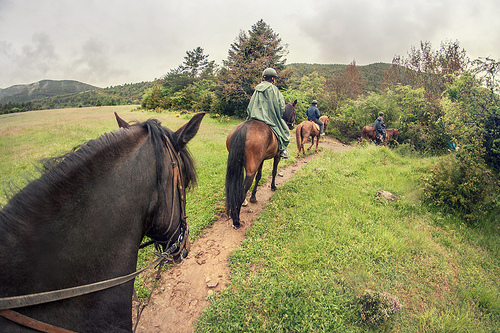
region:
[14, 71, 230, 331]
this is a horse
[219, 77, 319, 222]
this a brown horse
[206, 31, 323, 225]
person riding a horse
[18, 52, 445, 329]
group of people riding horses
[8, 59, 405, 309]
horses walking on a trail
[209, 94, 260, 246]
black tail on horse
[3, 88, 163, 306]
black mane on horse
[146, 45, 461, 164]
green brush next to trail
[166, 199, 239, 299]
horse foot prints on trail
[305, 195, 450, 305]
A patch of green and brown grass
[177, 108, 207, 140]
A horse's ear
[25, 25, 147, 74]
Cloud cover in the sky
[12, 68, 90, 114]
Mountains in the distance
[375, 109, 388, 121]
The person is wearing a helmet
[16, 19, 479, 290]
this is a nature setting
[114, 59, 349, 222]
these are horse riders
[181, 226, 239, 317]
the trail is made of dirt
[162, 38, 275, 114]
these are trees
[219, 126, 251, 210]
the horses tail is long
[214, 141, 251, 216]
the horse's tail is black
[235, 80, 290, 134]
the person has a poncho on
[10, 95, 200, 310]
black horse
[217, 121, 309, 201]
brown horse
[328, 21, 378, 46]
white clouds in blue sky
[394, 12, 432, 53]
white clouds in blue sky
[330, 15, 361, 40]
white clouds in blue sky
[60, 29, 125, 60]
white clouds in blue sky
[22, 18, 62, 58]
white clouds in blue sky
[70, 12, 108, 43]
white clouds in blue sky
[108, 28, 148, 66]
white clouds in blue sky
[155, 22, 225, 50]
white clouds in blue sky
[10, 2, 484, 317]
People riding horses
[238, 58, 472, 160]
The riders are wearing helmets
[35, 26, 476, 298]
The horses are on a dirt path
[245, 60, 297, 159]
This person is in a green jacket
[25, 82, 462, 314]
Most of the ground is covered in grass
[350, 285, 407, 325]
Small pink flowers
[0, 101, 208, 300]
Bridle on the horse's head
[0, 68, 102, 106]
A big mountain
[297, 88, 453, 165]
The horses are walking downhill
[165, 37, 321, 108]
A group of trees